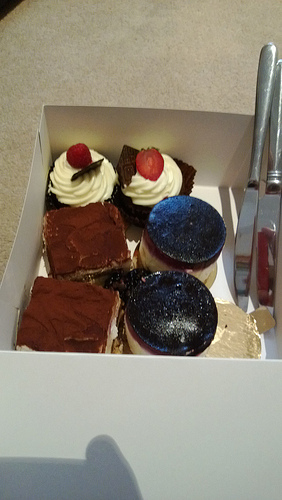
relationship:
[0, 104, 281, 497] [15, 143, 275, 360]
box filled with desserts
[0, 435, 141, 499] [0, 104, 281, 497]
shadow on box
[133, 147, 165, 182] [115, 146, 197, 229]
strawberry on cupcake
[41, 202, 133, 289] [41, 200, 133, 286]
slice of cake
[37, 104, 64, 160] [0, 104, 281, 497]
corner of box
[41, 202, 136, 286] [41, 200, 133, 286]
piece of cake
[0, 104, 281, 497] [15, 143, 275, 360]
box filled with pastries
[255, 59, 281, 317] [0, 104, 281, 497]
butter knife in box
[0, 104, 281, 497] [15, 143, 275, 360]
box of desserts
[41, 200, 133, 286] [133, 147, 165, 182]
cake has a strawberry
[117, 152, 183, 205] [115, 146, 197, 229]
whipped cream on cupcake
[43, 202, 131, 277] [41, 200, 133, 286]
frosting on cake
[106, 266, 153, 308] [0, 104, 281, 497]
berries in box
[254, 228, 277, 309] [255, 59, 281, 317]
reflection in butter knife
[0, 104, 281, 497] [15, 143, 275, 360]
box holding desserts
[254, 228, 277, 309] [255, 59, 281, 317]
reflection on butter knife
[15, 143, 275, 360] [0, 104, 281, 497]
desserts in box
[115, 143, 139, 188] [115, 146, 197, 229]
chocolate wafer on cupcake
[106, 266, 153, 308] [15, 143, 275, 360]
berries between desserts